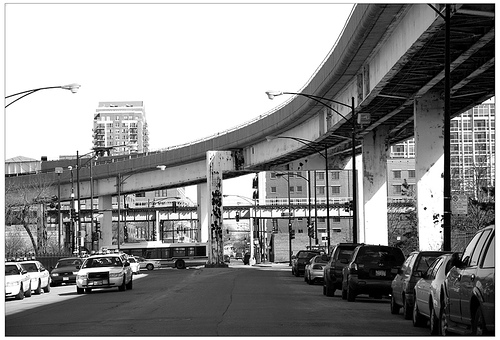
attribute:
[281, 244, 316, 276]
car — Parked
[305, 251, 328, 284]
car — Parked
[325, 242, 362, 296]
car — Parked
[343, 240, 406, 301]
car — Parked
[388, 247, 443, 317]
car — Parked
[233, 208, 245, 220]
traffic light — Lit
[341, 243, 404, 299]
vehicle — Parked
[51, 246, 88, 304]
car — parked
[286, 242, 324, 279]
car — Parked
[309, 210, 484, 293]
cars — Parked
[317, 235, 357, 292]
vehicle — Parked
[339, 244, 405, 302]
car — Parked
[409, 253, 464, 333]
vehicle — Parked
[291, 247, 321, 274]
vehicle — Parked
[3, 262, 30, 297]
vehicle — Parked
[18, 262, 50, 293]
vehicle — Parked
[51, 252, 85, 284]
vehicle — Parked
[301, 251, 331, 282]
car — Parked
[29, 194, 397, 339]
road — Black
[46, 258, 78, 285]
car — Parked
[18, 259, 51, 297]
vehicle — Parked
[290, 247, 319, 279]
car — Parked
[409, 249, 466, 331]
car — Parked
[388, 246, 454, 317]
car — Parked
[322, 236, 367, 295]
car — Parked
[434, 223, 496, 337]
car — Parked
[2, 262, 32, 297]
police cars — Parked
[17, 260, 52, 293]
police cars — Parked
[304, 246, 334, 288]
car — Parked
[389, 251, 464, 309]
vehicle — Parked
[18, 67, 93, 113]
street light — Lit